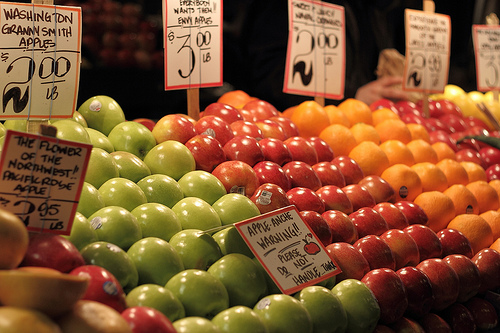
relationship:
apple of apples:
[0, 94, 500, 333] [18, 119, 359, 329]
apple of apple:
[0, 94, 500, 333] [184, 133, 222, 174]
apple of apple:
[0, 94, 500, 333] [284, 135, 321, 162]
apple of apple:
[0, 94, 500, 333] [363, 173, 393, 203]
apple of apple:
[0, 94, 500, 333] [289, 183, 324, 214]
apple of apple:
[0, 94, 500, 333] [382, 232, 417, 264]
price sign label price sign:
[161, 0, 226, 91] [162, 0, 224, 91]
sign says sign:
[288, 5, 345, 97] [283, 0, 345, 100]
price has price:
[402, 8, 451, 94] [407, 7, 450, 96]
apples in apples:
[0, 95, 381, 333] [0, 95, 381, 333]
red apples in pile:
[262, 148, 354, 210] [159, 83, 495, 301]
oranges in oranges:
[296, 89, 495, 261] [283, 97, 500, 257]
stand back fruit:
[0, 2, 498, 332] [29, 92, 374, 322]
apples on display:
[14, 95, 321, 332] [4, 87, 497, 331]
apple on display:
[13, 80, 498, 332] [4, 87, 497, 331]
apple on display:
[0, 94, 500, 333] [4, 87, 497, 331]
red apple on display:
[287, 157, 319, 197] [4, 87, 497, 331]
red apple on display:
[311, 159, 338, 180] [4, 87, 497, 331]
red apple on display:
[317, 184, 348, 211] [4, 87, 497, 331]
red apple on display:
[340, 180, 371, 206] [4, 87, 497, 331]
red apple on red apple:
[370, 201, 410, 233] [287, 157, 319, 197]